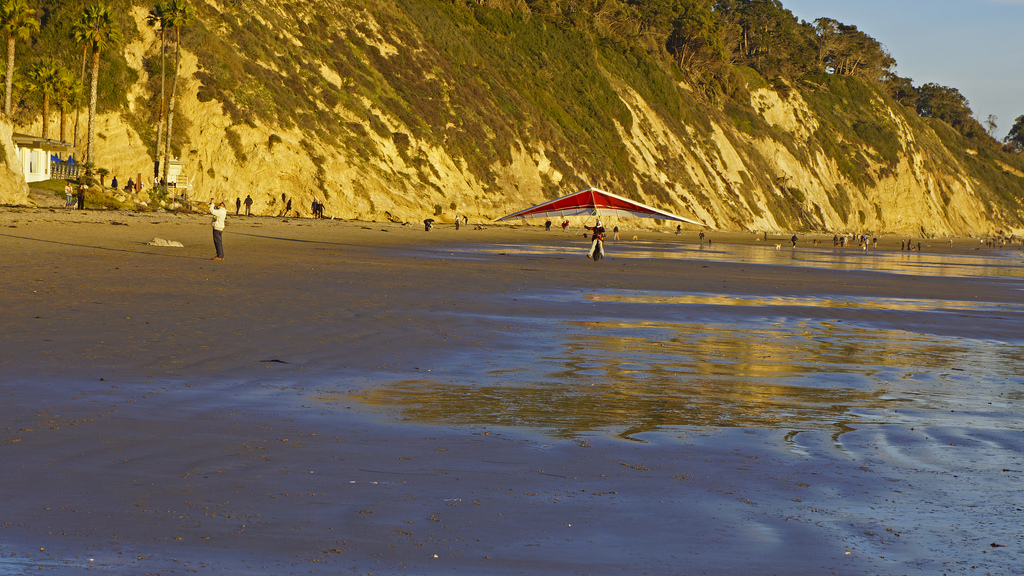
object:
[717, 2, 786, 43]
green leaves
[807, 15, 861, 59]
green leaves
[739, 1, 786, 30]
green leaves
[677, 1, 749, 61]
tree leaves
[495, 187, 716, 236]
kite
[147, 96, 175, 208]
tall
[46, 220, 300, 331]
beach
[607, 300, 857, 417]
reflections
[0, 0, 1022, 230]
cliff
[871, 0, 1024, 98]
sky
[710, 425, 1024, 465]
waves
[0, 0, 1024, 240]
hillside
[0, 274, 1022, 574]
water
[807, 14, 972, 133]
trees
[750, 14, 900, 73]
leaves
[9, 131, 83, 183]
building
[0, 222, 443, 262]
sand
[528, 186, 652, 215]
wing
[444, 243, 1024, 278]
reflection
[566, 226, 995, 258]
sand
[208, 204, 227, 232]
shirt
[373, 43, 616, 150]
grass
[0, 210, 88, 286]
exterior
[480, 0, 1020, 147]
trees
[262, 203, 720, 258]
hillside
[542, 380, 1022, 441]
ripples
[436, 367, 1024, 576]
sand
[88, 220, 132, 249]
air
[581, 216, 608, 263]
person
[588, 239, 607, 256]
pants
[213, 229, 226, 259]
pants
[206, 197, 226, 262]
person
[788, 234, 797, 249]
person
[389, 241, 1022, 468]
distance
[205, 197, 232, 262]
person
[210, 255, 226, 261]
shoes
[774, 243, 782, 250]
tan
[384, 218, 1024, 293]
beach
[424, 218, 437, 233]
person